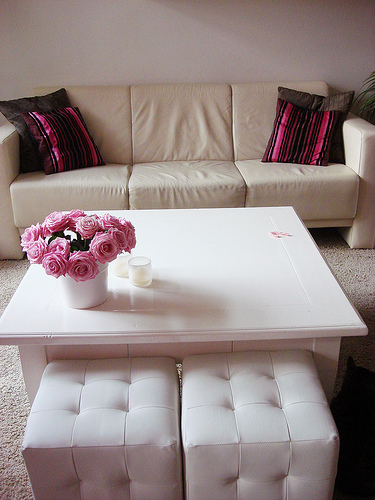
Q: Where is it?
A: This is at the living room.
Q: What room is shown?
A: It is a living room.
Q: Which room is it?
A: It is a living room.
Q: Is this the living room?
A: Yes, it is the living room.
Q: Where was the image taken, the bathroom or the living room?
A: It was taken at the living room.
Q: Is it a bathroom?
A: No, it is a living room.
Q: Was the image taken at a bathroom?
A: No, the picture was taken in a living room.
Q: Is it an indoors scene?
A: Yes, it is indoors.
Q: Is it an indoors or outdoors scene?
A: It is indoors.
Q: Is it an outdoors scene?
A: No, it is indoors.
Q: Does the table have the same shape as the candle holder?
A: No, the candle holder is round and the table is square.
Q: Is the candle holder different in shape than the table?
A: Yes, the candle holder is round and the table is square.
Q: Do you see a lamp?
A: No, there are no lamps.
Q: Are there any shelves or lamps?
A: No, there are no lamps or shelves.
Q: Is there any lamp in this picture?
A: No, there are no lamps.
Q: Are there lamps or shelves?
A: No, there are no lamps or shelves.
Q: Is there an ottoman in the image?
A: Yes, there is an ottoman.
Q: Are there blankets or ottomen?
A: Yes, there is an ottoman.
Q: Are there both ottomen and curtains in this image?
A: No, there is an ottoman but no curtains.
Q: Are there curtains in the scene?
A: No, there are no curtains.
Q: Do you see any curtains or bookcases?
A: No, there are no curtains or bookcases.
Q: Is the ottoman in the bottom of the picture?
A: Yes, the ottoman is in the bottom of the image.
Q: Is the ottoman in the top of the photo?
A: No, the ottoman is in the bottom of the image.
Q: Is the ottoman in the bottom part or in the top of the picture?
A: The ottoman is in the bottom of the image.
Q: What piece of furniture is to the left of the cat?
A: The piece of furniture is an ottoman.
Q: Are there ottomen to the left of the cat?
A: Yes, there is an ottoman to the left of the cat.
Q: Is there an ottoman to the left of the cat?
A: Yes, there is an ottoman to the left of the cat.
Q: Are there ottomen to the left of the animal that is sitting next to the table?
A: Yes, there is an ottoman to the left of the cat.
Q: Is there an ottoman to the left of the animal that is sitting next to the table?
A: Yes, there is an ottoman to the left of the cat.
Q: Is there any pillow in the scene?
A: Yes, there is a pillow.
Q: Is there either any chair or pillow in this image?
A: Yes, there is a pillow.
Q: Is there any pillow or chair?
A: Yes, there is a pillow.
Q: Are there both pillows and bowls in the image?
A: No, there is a pillow but no bowls.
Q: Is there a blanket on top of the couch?
A: No, there is a pillow on top of the couch.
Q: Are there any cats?
A: Yes, there is a cat.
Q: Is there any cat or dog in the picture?
A: Yes, there is a cat.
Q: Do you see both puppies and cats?
A: No, there is a cat but no puppies.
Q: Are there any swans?
A: No, there are no swans.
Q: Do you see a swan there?
A: No, there are no swans.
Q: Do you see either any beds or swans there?
A: No, there are no swans or beds.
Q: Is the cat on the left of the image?
A: No, the cat is on the right of the image.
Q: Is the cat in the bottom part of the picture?
A: Yes, the cat is in the bottom of the image.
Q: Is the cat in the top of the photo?
A: No, the cat is in the bottom of the image.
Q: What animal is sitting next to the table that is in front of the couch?
A: The cat is sitting next to the table.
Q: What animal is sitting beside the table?
A: The cat is sitting next to the table.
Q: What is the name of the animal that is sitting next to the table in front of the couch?
A: The animal is a cat.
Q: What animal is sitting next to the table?
A: The animal is a cat.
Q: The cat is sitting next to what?
A: The cat is sitting next to the table.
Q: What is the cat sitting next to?
A: The cat is sitting next to the table.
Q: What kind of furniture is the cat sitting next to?
A: The cat is sitting next to the table.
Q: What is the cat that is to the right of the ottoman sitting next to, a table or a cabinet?
A: The cat is sitting next to a table.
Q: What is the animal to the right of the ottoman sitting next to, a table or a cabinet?
A: The cat is sitting next to a table.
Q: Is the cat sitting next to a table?
A: Yes, the cat is sitting next to a table.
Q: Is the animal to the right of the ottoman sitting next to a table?
A: Yes, the cat is sitting next to a table.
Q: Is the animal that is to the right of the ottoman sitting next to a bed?
A: No, the cat is sitting next to a table.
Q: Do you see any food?
A: No, there is no food.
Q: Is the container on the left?
A: Yes, the container is on the left of the image.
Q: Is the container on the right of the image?
A: No, the container is on the left of the image.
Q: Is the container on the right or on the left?
A: The container is on the left of the image.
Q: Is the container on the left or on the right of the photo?
A: The container is on the left of the image.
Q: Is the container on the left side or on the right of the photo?
A: The container is on the left of the image.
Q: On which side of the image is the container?
A: The container is on the left of the image.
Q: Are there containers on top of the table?
A: Yes, there is a container on top of the table.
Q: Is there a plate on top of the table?
A: No, there is a container on top of the table.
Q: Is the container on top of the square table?
A: Yes, the container is on top of the table.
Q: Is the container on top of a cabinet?
A: No, the container is on top of the table.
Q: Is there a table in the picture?
A: Yes, there is a table.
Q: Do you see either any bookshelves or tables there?
A: Yes, there is a table.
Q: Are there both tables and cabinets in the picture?
A: No, there is a table but no cabinets.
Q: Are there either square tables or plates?
A: Yes, there is a square table.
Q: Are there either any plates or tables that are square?
A: Yes, the table is square.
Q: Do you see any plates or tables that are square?
A: Yes, the table is square.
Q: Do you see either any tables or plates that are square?
A: Yes, the table is square.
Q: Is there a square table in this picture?
A: Yes, there is a square table.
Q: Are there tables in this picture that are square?
A: Yes, there is a table that is square.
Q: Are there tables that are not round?
A: Yes, there is a square table.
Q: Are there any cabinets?
A: No, there are no cabinets.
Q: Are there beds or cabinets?
A: No, there are no cabinets or beds.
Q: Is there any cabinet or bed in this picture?
A: No, there are no cabinets or beds.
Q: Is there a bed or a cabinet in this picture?
A: No, there are no cabinets or beds.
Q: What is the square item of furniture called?
A: The piece of furniture is a table.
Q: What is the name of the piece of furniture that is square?
A: The piece of furniture is a table.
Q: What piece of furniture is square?
A: The piece of furniture is a table.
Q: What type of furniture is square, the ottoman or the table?
A: The table is square.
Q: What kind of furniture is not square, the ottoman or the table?
A: The ottoman is not square.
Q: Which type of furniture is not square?
A: The furniture is an ottoman.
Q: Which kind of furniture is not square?
A: The furniture is an ottoman.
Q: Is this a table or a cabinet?
A: This is a table.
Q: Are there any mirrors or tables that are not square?
A: No, there is a table but it is square.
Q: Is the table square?
A: Yes, the table is square.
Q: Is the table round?
A: No, the table is square.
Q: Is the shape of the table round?
A: No, the table is square.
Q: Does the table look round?
A: No, the table is square.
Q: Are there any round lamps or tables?
A: No, there is a table but it is square.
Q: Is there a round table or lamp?
A: No, there is a table but it is square.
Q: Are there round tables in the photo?
A: No, there is a table but it is square.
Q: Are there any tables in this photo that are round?
A: No, there is a table but it is square.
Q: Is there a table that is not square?
A: No, there is a table but it is square.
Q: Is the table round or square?
A: The table is square.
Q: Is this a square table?
A: Yes, this is a square table.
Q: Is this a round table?
A: No, this is a square table.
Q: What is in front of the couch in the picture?
A: The table is in front of the couch.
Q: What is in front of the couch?
A: The table is in front of the couch.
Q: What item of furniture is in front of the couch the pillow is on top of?
A: The piece of furniture is a table.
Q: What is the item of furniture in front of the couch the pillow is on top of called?
A: The piece of furniture is a table.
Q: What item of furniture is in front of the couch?
A: The piece of furniture is a table.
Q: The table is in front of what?
A: The table is in front of the couch.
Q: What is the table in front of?
A: The table is in front of the couch.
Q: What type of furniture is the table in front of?
A: The table is in front of the couch.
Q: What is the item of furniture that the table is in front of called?
A: The piece of furniture is a couch.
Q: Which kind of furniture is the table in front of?
A: The table is in front of the couch.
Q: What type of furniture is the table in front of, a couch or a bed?
A: The table is in front of a couch.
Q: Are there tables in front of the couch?
A: Yes, there is a table in front of the couch.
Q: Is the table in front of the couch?
A: Yes, the table is in front of the couch.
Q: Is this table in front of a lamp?
A: No, the table is in front of the couch.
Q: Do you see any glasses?
A: No, there are no glasses.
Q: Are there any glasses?
A: No, there are no glasses.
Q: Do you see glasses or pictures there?
A: No, there are no glasses or pictures.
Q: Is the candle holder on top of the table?
A: Yes, the candle holder is on top of the table.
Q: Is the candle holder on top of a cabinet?
A: No, the candle holder is on top of the table.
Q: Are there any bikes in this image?
A: No, there are no bikes.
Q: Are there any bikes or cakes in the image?
A: No, there are no bikes or cakes.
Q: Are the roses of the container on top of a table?
A: Yes, the roses are on top of a table.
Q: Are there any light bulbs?
A: No, there are no light bulbs.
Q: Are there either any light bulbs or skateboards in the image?
A: No, there are no light bulbs or skateboards.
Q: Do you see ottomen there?
A: Yes, there is an ottoman.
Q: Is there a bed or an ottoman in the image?
A: Yes, there is an ottoman.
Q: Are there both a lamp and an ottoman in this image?
A: No, there is an ottoman but no lamps.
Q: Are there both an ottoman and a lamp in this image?
A: No, there is an ottoman but no lamps.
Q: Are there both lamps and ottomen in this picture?
A: No, there is an ottoman but no lamps.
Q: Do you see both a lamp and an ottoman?
A: No, there is an ottoman but no lamps.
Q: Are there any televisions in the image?
A: No, there are no televisions.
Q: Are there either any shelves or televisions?
A: No, there are no televisions or shelves.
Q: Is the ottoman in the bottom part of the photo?
A: Yes, the ottoman is in the bottom of the image.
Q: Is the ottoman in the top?
A: No, the ottoman is in the bottom of the image.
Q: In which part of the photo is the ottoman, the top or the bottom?
A: The ottoman is in the bottom of the image.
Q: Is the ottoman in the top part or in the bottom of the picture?
A: The ottoman is in the bottom of the image.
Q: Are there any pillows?
A: Yes, there is a pillow.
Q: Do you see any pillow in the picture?
A: Yes, there is a pillow.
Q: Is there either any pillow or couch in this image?
A: Yes, there is a pillow.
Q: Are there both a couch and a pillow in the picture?
A: Yes, there are both a pillow and a couch.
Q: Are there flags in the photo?
A: No, there are no flags.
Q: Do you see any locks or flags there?
A: No, there are no flags or locks.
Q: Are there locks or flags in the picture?
A: No, there are no flags or locks.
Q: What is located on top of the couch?
A: The pillow is on top of the couch.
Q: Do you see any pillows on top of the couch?
A: Yes, there is a pillow on top of the couch.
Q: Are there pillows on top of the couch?
A: Yes, there is a pillow on top of the couch.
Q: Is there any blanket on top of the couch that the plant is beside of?
A: No, there is a pillow on top of the couch.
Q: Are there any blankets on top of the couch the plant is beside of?
A: No, there is a pillow on top of the couch.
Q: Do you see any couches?
A: Yes, there is a couch.